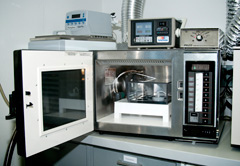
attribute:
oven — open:
[4, 49, 225, 160]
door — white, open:
[5, 50, 95, 159]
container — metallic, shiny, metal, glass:
[124, 81, 172, 105]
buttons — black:
[188, 72, 208, 125]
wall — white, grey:
[1, 0, 227, 166]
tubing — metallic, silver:
[122, 1, 240, 57]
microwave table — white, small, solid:
[114, 97, 172, 121]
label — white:
[123, 155, 138, 164]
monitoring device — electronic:
[128, 18, 183, 49]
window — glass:
[41, 68, 86, 132]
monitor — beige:
[180, 28, 227, 51]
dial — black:
[196, 34, 203, 41]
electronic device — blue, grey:
[65, 9, 113, 39]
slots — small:
[177, 81, 184, 102]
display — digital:
[192, 63, 210, 72]